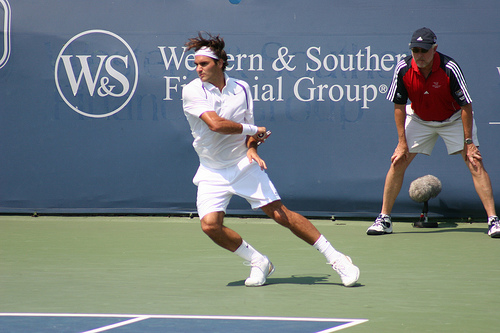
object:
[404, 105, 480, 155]
shorts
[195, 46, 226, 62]
band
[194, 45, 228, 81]
head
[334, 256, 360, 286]
feet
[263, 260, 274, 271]
heel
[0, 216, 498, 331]
ground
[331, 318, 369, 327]
edge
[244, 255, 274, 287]
shoes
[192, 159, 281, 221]
shorts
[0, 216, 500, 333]
floor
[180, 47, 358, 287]
man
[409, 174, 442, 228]
microphone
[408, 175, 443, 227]
thing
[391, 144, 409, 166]
hands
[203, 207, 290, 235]
knees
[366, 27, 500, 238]
ball boy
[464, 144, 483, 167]
hand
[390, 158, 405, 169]
knee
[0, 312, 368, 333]
lines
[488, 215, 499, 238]
shoe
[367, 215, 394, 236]
shoe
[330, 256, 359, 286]
shoe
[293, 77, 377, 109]
word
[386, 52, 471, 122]
shirt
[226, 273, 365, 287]
shadow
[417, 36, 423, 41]
logo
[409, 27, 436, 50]
cap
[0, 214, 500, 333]
court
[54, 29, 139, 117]
circle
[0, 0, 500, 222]
wall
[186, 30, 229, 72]
hair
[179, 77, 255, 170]
t shirt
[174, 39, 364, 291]
pro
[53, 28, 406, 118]
sponsor ad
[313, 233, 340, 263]
sock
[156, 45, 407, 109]
writing